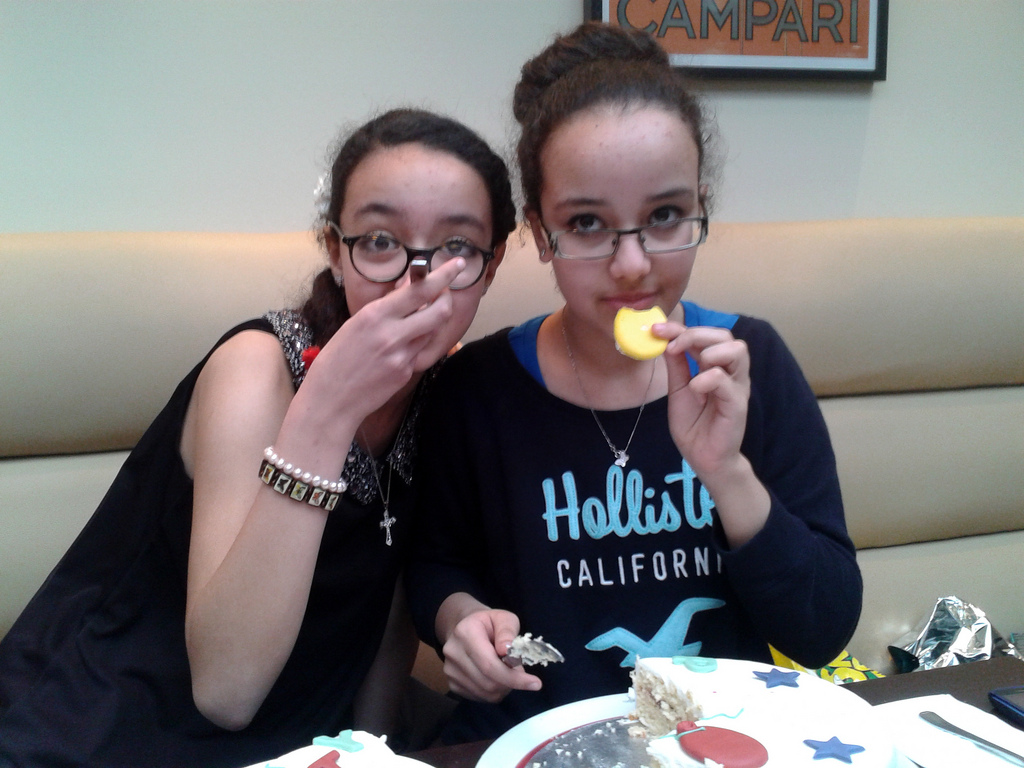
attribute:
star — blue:
[795, 728, 866, 764]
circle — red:
[668, 715, 766, 766]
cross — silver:
[372, 500, 405, 549]